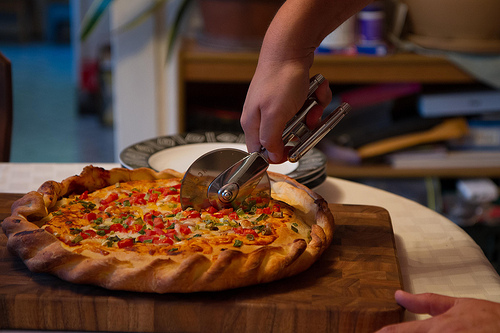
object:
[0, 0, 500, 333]
scene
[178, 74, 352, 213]
pizza cutter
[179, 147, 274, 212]
blade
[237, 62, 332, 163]
hand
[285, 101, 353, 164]
handle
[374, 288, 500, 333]
left hand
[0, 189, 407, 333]
cutting board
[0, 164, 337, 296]
pizza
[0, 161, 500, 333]
table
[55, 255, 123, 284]
crust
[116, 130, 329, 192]
stack of plates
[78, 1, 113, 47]
leaves of a plant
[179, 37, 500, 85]
desk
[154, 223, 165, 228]
red peppers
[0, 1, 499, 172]
background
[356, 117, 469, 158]
cooking utensil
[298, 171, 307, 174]
dark rim